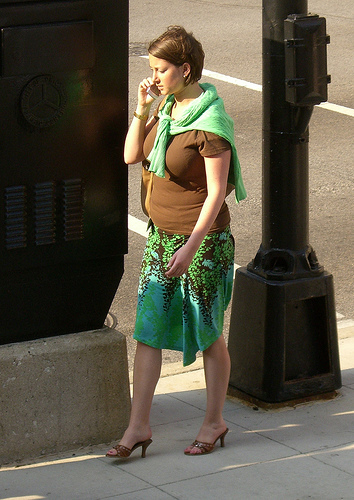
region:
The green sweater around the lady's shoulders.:
[137, 92, 258, 209]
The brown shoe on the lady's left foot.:
[104, 435, 154, 460]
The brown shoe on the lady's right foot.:
[175, 414, 229, 462]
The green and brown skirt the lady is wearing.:
[143, 224, 230, 350]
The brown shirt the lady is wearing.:
[145, 110, 237, 244]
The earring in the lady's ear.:
[180, 72, 189, 77]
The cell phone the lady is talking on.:
[143, 75, 162, 102]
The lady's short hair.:
[150, 31, 210, 74]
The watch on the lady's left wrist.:
[132, 111, 151, 123]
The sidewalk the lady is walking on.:
[22, 424, 290, 496]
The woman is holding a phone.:
[114, 28, 241, 182]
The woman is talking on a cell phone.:
[111, 19, 233, 199]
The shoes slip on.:
[94, 408, 238, 465]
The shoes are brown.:
[95, 412, 239, 470]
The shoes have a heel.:
[96, 420, 259, 468]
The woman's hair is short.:
[143, 24, 207, 96]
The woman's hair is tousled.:
[138, 18, 214, 100]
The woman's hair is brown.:
[144, 18, 210, 99]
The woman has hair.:
[138, 23, 212, 102]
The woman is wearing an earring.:
[137, 18, 206, 102]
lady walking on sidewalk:
[118, 9, 249, 497]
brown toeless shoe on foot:
[164, 419, 239, 462]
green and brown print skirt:
[138, 227, 224, 366]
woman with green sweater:
[136, 19, 247, 202]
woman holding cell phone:
[132, 36, 226, 175]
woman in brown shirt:
[141, 25, 252, 236]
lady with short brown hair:
[134, 23, 223, 143]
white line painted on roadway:
[211, 68, 286, 118]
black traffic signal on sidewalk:
[245, 1, 352, 423]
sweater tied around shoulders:
[133, 23, 255, 220]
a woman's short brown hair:
[146, 38, 205, 79]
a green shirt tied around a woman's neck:
[147, 99, 277, 220]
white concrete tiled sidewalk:
[240, 422, 331, 497]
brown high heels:
[108, 435, 259, 459]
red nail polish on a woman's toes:
[105, 447, 119, 457]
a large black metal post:
[251, 0, 339, 390]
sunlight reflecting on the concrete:
[31, 445, 81, 466]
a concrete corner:
[4, 334, 138, 465]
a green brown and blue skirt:
[114, 212, 238, 366]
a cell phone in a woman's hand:
[142, 79, 166, 98]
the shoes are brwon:
[106, 433, 156, 462]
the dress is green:
[135, 304, 218, 343]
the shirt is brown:
[133, 134, 244, 220]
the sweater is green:
[186, 101, 246, 152]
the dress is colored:
[143, 254, 232, 331]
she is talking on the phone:
[139, 40, 238, 285]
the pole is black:
[259, 103, 333, 252]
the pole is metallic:
[266, 98, 315, 220]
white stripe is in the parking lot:
[214, 62, 255, 97]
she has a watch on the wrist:
[130, 108, 151, 121]